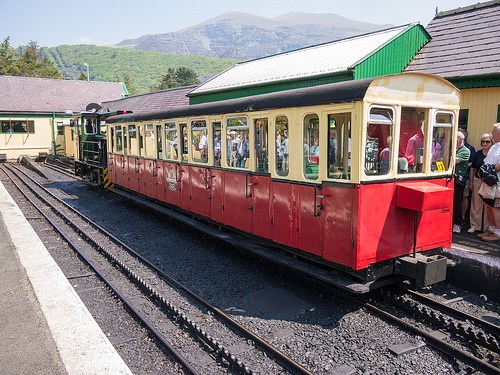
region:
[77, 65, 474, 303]
Train on tracks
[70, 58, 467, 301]
Train is on tracks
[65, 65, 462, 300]
Train on train tracks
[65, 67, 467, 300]
Train is on train tracks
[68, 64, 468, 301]
Train on railroad tracks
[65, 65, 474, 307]
Train is on railroad tracks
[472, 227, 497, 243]
Man wearing brown shoes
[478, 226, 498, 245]
Man is wearing brown shoes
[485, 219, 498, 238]
Man wearing white socks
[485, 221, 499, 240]
Man is wearing white socks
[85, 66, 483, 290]
red and yellow train car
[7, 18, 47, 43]
white clouds in blue sky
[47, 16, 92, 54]
white clouds in blue sky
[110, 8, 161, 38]
white clouds in blue sky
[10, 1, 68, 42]
white clouds in blue sky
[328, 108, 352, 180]
back corner window on the train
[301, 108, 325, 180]
second to last window on the train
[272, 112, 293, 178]
third to last window on the train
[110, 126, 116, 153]
first window on the train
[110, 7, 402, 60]
mountain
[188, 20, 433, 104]
green roof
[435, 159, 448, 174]
yellow square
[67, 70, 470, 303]
train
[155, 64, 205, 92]
top of a tree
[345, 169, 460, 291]
red front portion of train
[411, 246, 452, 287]
black attachment on front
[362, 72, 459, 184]
faded yellow top of train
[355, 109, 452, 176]
front windows on train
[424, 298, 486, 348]
black train track on grond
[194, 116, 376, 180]
windows on side of train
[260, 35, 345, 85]
black roof on building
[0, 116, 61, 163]
tan side of building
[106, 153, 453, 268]
The bottom of the train car is red.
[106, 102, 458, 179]
The top of the train car is beige.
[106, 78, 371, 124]
The roof of the train car is black.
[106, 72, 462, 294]
Red and beige train car.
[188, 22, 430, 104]
Green building with white roof.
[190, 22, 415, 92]
The green building has a white roof.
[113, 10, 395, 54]
Mountain in the background.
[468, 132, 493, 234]
Woman in black with sunglasses.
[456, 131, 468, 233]
Man in green shirt waiting for the train.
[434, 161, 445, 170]
Yellow number 12 sign in back of train window.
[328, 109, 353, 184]
Window of a train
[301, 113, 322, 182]
Window of a train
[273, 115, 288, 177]
Window of a train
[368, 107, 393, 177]
Window of a train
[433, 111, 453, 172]
Window of a train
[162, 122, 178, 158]
Window of a train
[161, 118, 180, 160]
Window of a train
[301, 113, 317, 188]
Window of a train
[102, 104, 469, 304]
a Passenger car on the train track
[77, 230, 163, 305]
A section of train track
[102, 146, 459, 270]
The orange part of the train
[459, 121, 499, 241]
People waiting to get on the train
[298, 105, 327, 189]
A window on the train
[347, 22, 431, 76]
the green part of the roof